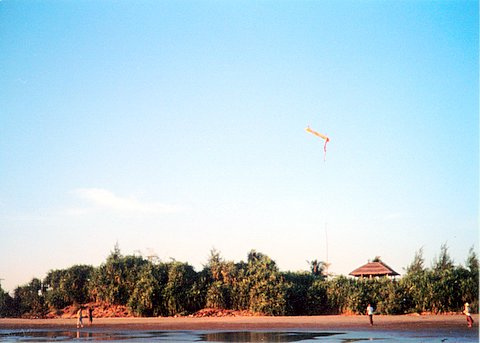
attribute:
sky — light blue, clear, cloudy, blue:
[0, 1, 479, 274]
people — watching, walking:
[67, 297, 476, 329]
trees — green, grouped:
[0, 242, 480, 313]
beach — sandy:
[2, 315, 479, 329]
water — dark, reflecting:
[2, 324, 477, 342]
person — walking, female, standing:
[360, 299, 378, 328]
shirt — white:
[366, 306, 373, 315]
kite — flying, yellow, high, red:
[303, 123, 331, 155]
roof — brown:
[345, 256, 398, 277]